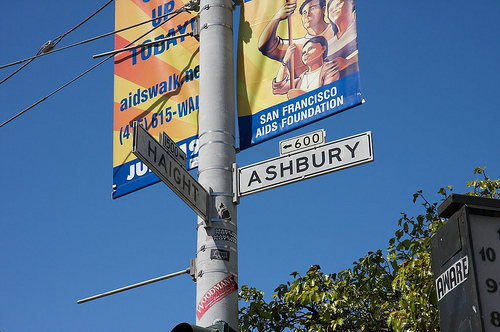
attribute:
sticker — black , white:
[426, 251, 475, 305]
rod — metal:
[66, 258, 193, 314]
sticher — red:
[193, 270, 245, 322]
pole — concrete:
[188, 1, 244, 330]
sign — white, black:
[126, 115, 220, 231]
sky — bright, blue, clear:
[5, 11, 493, 232]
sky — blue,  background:
[429, 41, 460, 108]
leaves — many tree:
[392, 279, 422, 309]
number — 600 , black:
[289, 132, 326, 150]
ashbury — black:
[244, 142, 367, 184]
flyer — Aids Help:
[112, 3, 371, 189]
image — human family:
[258, 6, 351, 100]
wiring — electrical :
[4, 3, 192, 141]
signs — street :
[234, 126, 380, 197]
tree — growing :
[291, 180, 474, 321]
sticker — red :
[194, 277, 239, 319]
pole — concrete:
[194, 3, 244, 314]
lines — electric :
[1, 18, 190, 125]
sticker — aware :
[431, 251, 468, 301]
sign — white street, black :
[128, 114, 378, 218]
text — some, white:
[251, 83, 354, 132]